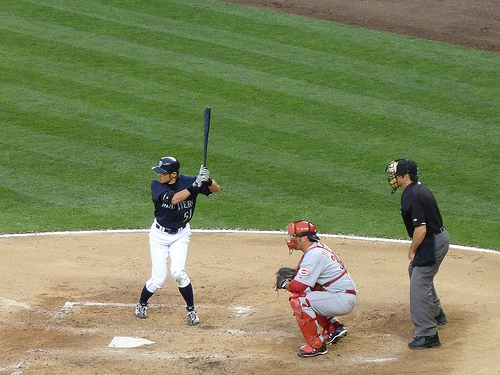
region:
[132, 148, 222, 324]
Batter getting ready to hit ball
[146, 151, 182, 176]
Black baseball cap helmet worn by batter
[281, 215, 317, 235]
Catcher wearing red helmet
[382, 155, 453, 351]
Umpire standing in back of catcher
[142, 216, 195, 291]
White pants worn by batter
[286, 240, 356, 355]
Red and white baseball outfit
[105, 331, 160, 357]
White home plate sitting in the sand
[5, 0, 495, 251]
Grass of baseball field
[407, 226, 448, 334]
Gray pants worn by umpire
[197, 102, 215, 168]
Bat held by batter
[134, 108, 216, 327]
Batter is waiting to hit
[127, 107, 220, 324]
batter is holding a bat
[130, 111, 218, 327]
batter wearing blue helmet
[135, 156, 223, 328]
batter wearing blue shirt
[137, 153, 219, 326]
batter wearing white pants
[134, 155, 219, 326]
batter wearing blue socks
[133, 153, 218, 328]
batter wearing white shoes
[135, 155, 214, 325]
batter wearing white gloves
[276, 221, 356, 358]
catcher wearing red pads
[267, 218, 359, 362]
catcher wearing gray uniform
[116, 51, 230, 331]
the man is batting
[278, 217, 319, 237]
the helmet is orange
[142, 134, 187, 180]
the helmet is black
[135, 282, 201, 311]
the socks are long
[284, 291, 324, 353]
the man is wearing shin guards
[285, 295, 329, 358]
the shin guards are orange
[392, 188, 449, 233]
the man is wearing a shirt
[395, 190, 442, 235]
the shirt is black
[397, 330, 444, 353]
the shoe is black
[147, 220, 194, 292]
the pants are white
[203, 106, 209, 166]
baseball bat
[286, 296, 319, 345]
baseball catcher's red kneepads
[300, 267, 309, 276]
Columbus Clippers team logo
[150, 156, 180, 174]
blue batter's helmet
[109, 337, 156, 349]
home ba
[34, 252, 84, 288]
a section of brown sand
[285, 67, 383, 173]
green grass trimmed in lines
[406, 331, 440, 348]
a pair of men's black work shoes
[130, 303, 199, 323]
a pair of white sport cleats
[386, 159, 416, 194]
baseball umpire's helmet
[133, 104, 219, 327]
this man is holding a baseball bat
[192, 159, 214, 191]
the man is wearing gloves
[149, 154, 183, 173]
the man is wearing a baseball cap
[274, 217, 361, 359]
the man is crouching on the ground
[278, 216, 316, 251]
the man is wearing a red helmet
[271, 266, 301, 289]
the man is wearing gloves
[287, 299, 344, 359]
the man is wearing red socks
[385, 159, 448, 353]
the man is standing at the back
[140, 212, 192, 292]
the man is wearing white pants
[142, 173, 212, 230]
the man is wearing a blue shirt